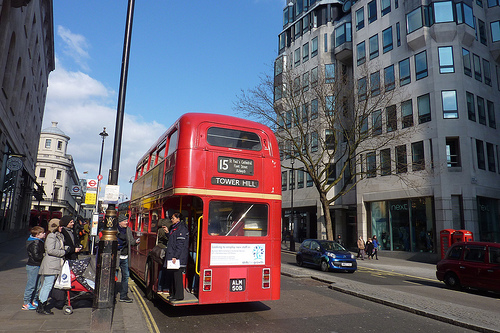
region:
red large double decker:
[136, 120, 309, 315]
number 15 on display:
[201, 149, 289, 187]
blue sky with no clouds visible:
[158, 65, 250, 106]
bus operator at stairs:
[155, 200, 204, 300]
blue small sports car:
[289, 223, 390, 313]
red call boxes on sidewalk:
[440, 212, 481, 278]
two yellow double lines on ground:
[125, 303, 172, 325]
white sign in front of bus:
[193, 230, 301, 286]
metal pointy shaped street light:
[81, 113, 113, 149]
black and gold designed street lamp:
[89, 178, 118, 320]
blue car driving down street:
[293, 233, 357, 270]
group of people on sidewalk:
[356, 233, 381, 260]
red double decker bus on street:
[126, 109, 285, 311]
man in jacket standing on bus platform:
[163, 209, 191, 301]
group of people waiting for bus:
[20, 212, 93, 317]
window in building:
[439, 86, 461, 121]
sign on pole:
[86, 176, 98, 190]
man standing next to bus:
[116, 208, 143, 305]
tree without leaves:
[232, 44, 439, 239]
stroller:
[61, 256, 95, 316]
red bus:
[137, 82, 321, 310]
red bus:
[138, 152, 276, 297]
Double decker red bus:
[127, 111, 284, 310]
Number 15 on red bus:
[216, 157, 229, 173]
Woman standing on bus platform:
[160, 212, 189, 299]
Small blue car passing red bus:
[292, 236, 357, 276]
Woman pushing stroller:
[37, 217, 64, 321]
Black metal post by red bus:
[100, 0, 135, 324]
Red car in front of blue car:
[435, 237, 499, 294]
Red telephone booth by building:
[435, 225, 450, 256]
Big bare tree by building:
[235, 61, 420, 250]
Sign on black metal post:
[102, 180, 121, 205]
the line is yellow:
[133, 305, 160, 327]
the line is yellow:
[137, 314, 163, 326]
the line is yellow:
[137, 299, 157, 322]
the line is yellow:
[134, 291, 147, 306]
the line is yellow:
[139, 302, 148, 316]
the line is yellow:
[143, 305, 159, 317]